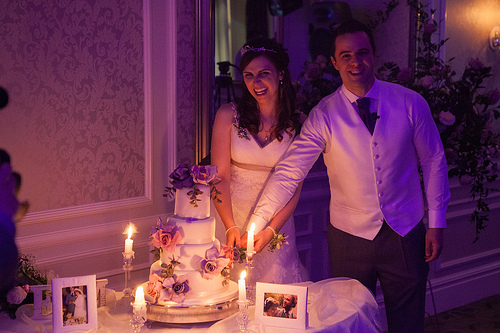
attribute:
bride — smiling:
[207, 37, 301, 270]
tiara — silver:
[237, 40, 290, 67]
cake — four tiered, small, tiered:
[148, 165, 240, 320]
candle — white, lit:
[116, 222, 146, 291]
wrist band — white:
[257, 223, 280, 241]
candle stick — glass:
[119, 257, 141, 315]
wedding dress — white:
[213, 100, 325, 295]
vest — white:
[296, 104, 425, 249]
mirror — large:
[403, 17, 498, 145]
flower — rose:
[438, 110, 456, 139]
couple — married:
[203, 29, 427, 300]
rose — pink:
[146, 225, 184, 257]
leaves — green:
[143, 251, 174, 285]